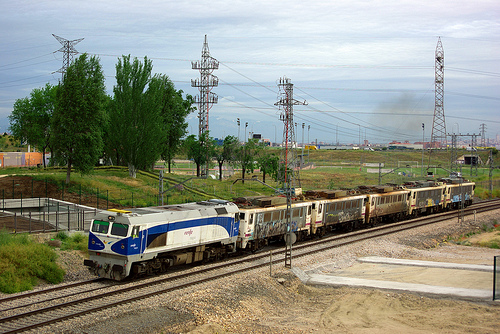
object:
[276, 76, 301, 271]
poles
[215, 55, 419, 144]
wires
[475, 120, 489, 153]
utility tower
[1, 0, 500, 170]
background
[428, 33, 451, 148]
tower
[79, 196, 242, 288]
train front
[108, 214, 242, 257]
swirl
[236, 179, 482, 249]
train cars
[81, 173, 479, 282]
train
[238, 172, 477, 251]
graffiti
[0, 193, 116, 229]
tunnel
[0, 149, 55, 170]
building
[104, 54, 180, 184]
trees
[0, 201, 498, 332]
gravel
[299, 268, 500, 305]
slabs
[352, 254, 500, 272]
slabs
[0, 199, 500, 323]
tracks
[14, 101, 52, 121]
leaves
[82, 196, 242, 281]
engine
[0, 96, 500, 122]
power lines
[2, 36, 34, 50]
air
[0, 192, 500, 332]
train tracks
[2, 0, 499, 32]
sky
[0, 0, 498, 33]
clouds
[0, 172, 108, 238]
opening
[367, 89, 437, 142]
smoke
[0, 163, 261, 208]
hill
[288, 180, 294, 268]
pole